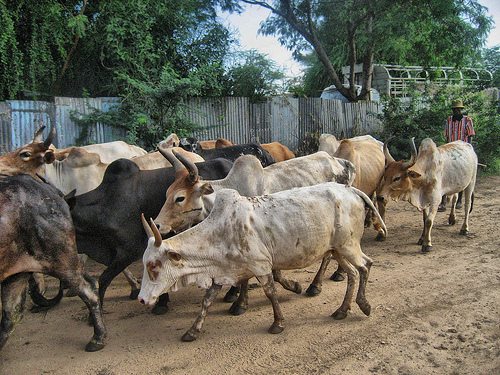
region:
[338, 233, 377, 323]
leg of a cow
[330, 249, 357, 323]
leg of a cow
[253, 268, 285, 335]
leg of a cow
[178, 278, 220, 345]
leg of a cow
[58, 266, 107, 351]
leg of a cow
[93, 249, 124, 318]
leg of a cow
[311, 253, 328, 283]
leg of a cow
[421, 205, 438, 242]
leg of a cow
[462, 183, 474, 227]
leg of a cow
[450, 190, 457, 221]
leg of a cow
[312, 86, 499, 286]
A man herding cow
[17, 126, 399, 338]
A group of cows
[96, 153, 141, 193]
Hump on a black cow's back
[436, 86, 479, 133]
A man wearing a hat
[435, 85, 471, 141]
A man wearing a striped shirt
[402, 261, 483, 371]
Dirt on the ground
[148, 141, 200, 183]
Two cow horns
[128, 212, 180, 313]
Head of a cow with horns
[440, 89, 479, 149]
A man wearing a hat an a striped shirt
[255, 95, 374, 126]
A fence made of metal sheets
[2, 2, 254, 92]
trees behind the fence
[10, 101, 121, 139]
white fence behind animals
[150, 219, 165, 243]
left horn on white animal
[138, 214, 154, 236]
right horn on animal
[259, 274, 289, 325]
left front leg on animal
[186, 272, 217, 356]
right front leg on animal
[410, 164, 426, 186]
left ear on horned animal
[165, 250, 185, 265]
left ear on animal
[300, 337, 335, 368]
sand on the ground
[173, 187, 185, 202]
left eye on humped animal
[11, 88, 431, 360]
The cattle are walking in the dirt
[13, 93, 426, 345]
The cattle belonging to a farmer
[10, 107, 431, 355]
The cattle are walking to somewhere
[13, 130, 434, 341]
Some cattle have very big horns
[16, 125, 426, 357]
The cattle are male and female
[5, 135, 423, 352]
The cattle are looking for food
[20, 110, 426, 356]
The cattle are being driven to market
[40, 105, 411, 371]
The cattle are out in the daytime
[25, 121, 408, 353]
The cattle are enjoying the day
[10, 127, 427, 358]
Some cattle have humps on their back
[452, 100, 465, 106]
hat on the man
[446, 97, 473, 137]
man tending bull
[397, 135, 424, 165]
horn on the bull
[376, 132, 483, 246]
bull walking on dirt road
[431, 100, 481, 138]
man next to bull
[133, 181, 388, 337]
bull on the dirt road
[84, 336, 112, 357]
hoof on the bull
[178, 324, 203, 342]
hoof on the bull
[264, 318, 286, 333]
hoof on the bull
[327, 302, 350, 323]
hoof on the bull